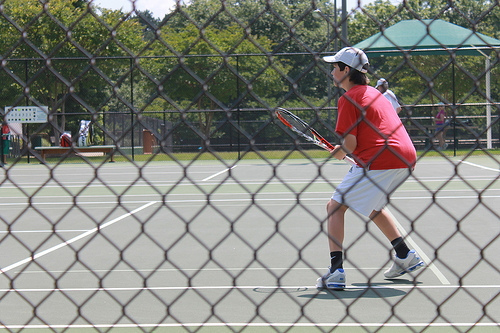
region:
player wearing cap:
[318, 48, 385, 70]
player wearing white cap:
[319, 43, 373, 70]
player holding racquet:
[267, 108, 350, 165]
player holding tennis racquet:
[271, 104, 348, 163]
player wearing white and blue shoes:
[311, 270, 348, 290]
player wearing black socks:
[331, 253, 345, 270]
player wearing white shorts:
[330, 163, 407, 208]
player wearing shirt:
[335, 91, 411, 167]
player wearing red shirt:
[335, 91, 410, 166]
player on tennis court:
[278, 45, 429, 293]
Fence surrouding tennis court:
[0, 0, 498, 331]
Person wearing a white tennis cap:
[312, 49, 424, 289]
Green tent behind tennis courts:
[344, 18, 497, 150]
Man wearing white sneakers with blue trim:
[315, 46, 424, 290]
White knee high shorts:
[332, 159, 413, 220]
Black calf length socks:
[321, 235, 409, 274]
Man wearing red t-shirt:
[315, 45, 424, 289]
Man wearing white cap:
[371, 77, 401, 116]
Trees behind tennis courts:
[1, 2, 499, 148]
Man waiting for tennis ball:
[274, 46, 426, 290]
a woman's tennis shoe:
[383, 250, 428, 282]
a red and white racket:
[272, 105, 354, 170]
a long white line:
[0, 281, 497, 291]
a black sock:
[387, 235, 403, 255]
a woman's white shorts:
[331, 163, 407, 219]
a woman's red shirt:
[330, 84, 421, 167]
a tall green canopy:
[340, 16, 499, 138]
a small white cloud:
[137, 0, 169, 11]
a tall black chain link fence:
[8, 45, 496, 150]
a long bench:
[35, 143, 116, 164]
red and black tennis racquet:
[267, 100, 345, 168]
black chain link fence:
[1, 2, 498, 332]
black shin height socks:
[328, 248, 345, 268]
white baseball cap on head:
[322, 45, 376, 75]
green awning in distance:
[347, 18, 498, 80]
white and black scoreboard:
[3, 102, 48, 126]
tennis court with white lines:
[0, 192, 497, 329]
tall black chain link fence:
[4, 52, 498, 161]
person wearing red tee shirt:
[328, 82, 421, 177]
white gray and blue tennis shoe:
[314, 266, 349, 294]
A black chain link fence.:
[0, 3, 498, 330]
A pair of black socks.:
[329, 237, 411, 265]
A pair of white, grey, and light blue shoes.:
[314, 250, 424, 290]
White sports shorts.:
[331, 165, 404, 216]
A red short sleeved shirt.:
[338, 87, 417, 167]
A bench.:
[31, 142, 118, 161]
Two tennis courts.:
[3, 155, 498, 331]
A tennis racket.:
[269, 102, 361, 171]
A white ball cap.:
[323, 47, 372, 72]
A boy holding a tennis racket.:
[271, 48, 443, 293]